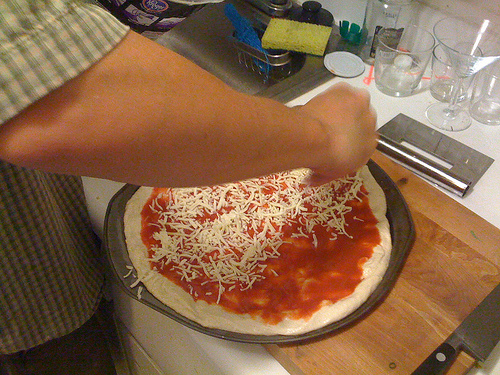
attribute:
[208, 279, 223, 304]
cheese — shredded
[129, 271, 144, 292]
cheese — shredded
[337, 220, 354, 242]
cheese — shredded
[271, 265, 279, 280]
cheese — shredded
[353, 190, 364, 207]
cheese — shredded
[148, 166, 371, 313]
pizza — fresh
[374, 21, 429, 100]
glass — small, empty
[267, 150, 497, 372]
board — wooden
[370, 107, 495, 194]
scraper — stainless steel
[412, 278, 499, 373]
knife — sharp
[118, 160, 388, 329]
pizza — raw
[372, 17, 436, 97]
container — clear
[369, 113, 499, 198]
chopper — metal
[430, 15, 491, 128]
glass — empty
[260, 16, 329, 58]
sponge — dirty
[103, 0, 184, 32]
stopper — black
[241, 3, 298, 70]
sponge holder — silver